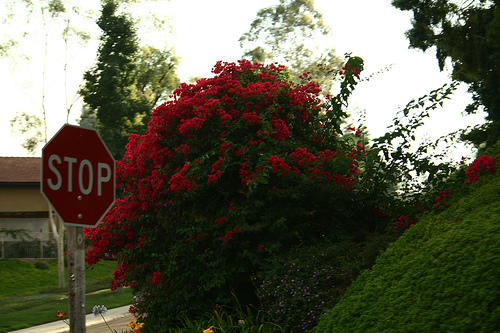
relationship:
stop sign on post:
[41, 124, 117, 227] [64, 221, 87, 332]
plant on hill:
[83, 57, 363, 314] [312, 183, 499, 333]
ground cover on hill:
[317, 181, 499, 331] [312, 183, 499, 333]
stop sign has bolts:
[41, 124, 117, 227] [77, 193, 82, 222]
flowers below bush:
[127, 319, 219, 332] [83, 54, 365, 333]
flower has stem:
[91, 305, 107, 316] [102, 315, 113, 332]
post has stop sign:
[64, 221, 87, 332] [41, 124, 117, 227]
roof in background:
[1, 158, 61, 213] [2, 0, 172, 331]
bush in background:
[464, 155, 495, 186] [298, 3, 498, 218]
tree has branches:
[1, 0, 98, 156] [1, 4, 94, 155]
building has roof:
[1, 156, 57, 257] [1, 158, 61, 213]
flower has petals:
[57, 310, 66, 320] [56, 310, 65, 319]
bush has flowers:
[83, 54, 365, 333] [84, 58, 365, 315]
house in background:
[1, 156, 57, 257] [2, 0, 172, 331]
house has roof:
[1, 156, 57, 257] [1, 158, 61, 213]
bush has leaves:
[83, 54, 365, 333] [132, 112, 382, 308]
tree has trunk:
[48, 203, 67, 288] [46, 202, 67, 286]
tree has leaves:
[392, 1, 499, 152] [392, 0, 499, 149]